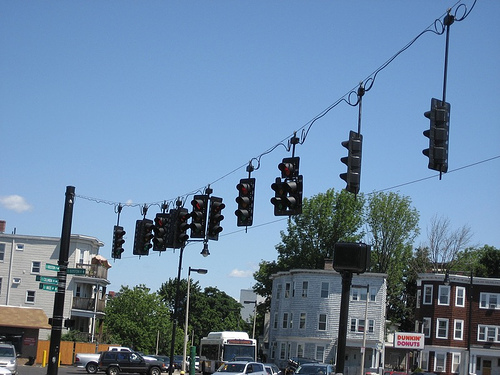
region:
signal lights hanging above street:
[104, 200, 175, 269]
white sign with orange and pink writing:
[387, 323, 454, 363]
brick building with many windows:
[412, 259, 497, 357]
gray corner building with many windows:
[258, 265, 400, 372]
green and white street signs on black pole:
[25, 249, 92, 374]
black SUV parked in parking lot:
[90, 345, 178, 372]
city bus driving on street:
[195, 326, 272, 374]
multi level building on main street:
[5, 205, 120, 365]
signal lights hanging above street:
[197, 118, 367, 272]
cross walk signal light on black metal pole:
[322, 228, 402, 371]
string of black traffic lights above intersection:
[62, 58, 461, 344]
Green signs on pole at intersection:
[38, 249, 86, 299]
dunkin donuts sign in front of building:
[393, 323, 428, 365]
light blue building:
[260, 261, 385, 368]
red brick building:
[413, 267, 495, 366]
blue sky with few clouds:
[6, 32, 49, 227]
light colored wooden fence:
[38, 336, 123, 364]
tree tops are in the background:
[109, 270, 244, 332]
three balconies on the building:
[68, 224, 110, 341]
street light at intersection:
[175, 260, 210, 368]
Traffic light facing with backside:
[410, 85, 467, 181]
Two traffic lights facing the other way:
[342, 13, 466, 196]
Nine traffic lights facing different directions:
[112, 25, 464, 260]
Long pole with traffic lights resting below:
[57, 2, 467, 264]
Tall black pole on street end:
[45, 171, 79, 371]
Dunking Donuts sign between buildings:
[386, 322, 435, 352]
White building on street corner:
[260, 265, 399, 370]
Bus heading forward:
[193, 325, 265, 372]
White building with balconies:
[0, 225, 117, 365]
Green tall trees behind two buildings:
[250, 190, 498, 343]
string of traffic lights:
[108, 98, 455, 261]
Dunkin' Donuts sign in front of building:
[391, 330, 425, 349]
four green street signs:
[35, 260, 87, 293]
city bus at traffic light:
[197, 329, 257, 374]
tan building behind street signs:
[0, 212, 112, 369]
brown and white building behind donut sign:
[408, 265, 496, 372]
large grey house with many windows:
[262, 255, 385, 373]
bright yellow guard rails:
[36, 347, 61, 369]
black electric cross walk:
[327, 235, 373, 374]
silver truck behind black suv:
[72, 343, 157, 372]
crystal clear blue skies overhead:
[92, 41, 225, 122]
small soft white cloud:
[220, 267, 255, 283]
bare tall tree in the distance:
[415, 217, 495, 277]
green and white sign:
[27, 251, 103, 283]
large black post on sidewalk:
[38, 175, 85, 345]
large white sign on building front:
[381, 324, 443, 358]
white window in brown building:
[435, 278, 477, 318]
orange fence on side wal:
[8, 315, 130, 373]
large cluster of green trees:
[282, 174, 447, 280]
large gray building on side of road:
[266, 257, 433, 363]